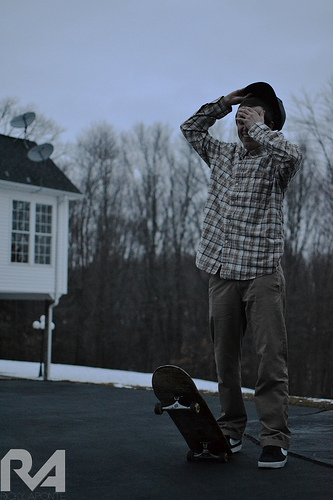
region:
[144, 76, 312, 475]
A kid standing on the end of a skateboard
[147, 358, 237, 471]
The bottom of a skateboard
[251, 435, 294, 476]
An athletic shoe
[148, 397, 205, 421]
The front wheels of a skateboard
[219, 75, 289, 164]
A boy with his hands on his face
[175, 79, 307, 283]
A boy wearing a button up shirt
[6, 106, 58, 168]
Discs on a roof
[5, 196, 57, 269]
A window of a house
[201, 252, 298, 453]
A pair of long pants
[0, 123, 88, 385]
A white house with a black roof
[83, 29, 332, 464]
a boy on a street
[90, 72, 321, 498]
a boy standing on a street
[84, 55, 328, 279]
a boy wearing a hat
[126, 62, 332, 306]
a boy wearing a shirt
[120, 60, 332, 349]
a boy wearing a long sleeve shirt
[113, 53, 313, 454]
a boy wearing pants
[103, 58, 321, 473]
a boy with a foot on the skateboard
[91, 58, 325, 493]
a skateboard on the ground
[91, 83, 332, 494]
a boy that is skateboarding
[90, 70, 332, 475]
a boy wearing shoes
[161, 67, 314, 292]
a boy wearing a brown squared shirt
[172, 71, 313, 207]
boy is touching his cap with his right hand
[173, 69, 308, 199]
bor covered his face with left hand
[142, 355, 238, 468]
a black skateboard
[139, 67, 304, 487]
boy holds his skateboard with right foot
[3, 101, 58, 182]
two satellites on roof of house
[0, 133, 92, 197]
roof oh house is black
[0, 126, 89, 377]
house is white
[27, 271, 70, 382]
column on a corner of a house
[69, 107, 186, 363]
tall trees on side a house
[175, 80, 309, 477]
This is a man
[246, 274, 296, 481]
Leg of a man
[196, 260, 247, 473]
Leg of a man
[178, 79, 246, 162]
Hand of a man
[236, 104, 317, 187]
Hand of a man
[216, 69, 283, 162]
Head of a man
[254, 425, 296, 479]
Feet of a man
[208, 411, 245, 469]
Feet of a man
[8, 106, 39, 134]
This is a satellite dish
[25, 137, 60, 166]
This is a satellite dish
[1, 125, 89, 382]
a white house with black roof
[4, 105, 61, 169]
two satellites color gray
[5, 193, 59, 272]
a window on corner of a house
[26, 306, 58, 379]
a pole with four lights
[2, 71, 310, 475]
a boy standing in front a white house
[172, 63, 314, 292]
boy wears a square shirt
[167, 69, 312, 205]
boy covers his face with left hand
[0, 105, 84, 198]
two satellites on a black roof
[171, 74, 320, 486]
boy touching a cap with his right arm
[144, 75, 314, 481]
boy step on border of a skateboard